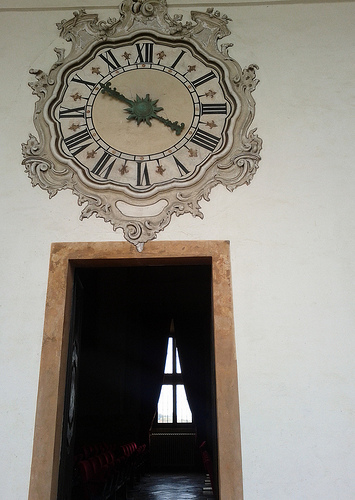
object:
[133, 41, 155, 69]
number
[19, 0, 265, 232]
clock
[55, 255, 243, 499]
door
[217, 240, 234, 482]
marble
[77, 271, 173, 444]
drapes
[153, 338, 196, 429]
window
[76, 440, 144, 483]
seats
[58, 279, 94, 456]
screen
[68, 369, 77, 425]
woman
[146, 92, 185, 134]
hands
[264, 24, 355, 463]
walls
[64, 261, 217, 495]
room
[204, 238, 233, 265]
corner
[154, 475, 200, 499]
reflection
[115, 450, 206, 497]
floor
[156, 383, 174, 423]
panes